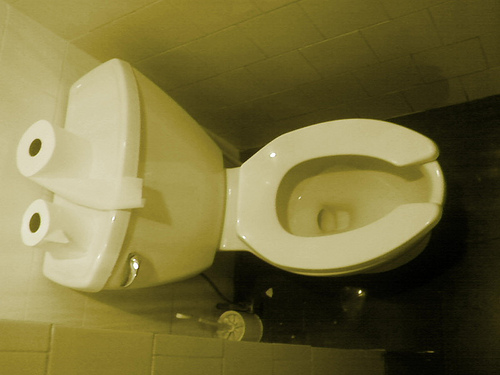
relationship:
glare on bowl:
[255, 151, 295, 166] [245, 142, 433, 254]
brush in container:
[176, 309, 264, 341] [216, 309, 264, 342]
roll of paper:
[19, 199, 78, 255] [8, 119, 96, 201]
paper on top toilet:
[18, 126, 117, 209] [115, 73, 222, 265]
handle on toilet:
[121, 254, 140, 287] [105, 74, 232, 271]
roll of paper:
[19, 199, 78, 255] [5, 112, 103, 251]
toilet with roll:
[43, 58, 447, 293] [19, 199, 78, 255]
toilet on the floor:
[43, 58, 447, 293] [431, 276, 461, 319]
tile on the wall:
[245, 50, 321, 94] [218, 6, 484, 117]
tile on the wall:
[249, 16, 295, 46] [216, 15, 451, 115]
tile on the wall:
[245, 50, 321, 94] [173, 0, 463, 108]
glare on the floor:
[327, 281, 399, 315] [428, 270, 467, 334]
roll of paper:
[19, 199, 78, 255] [60, 162, 140, 221]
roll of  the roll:
[31, 214, 40, 221] [19, 199, 78, 255]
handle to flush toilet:
[121, 254, 140, 287] [41, 49, 452, 319]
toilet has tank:
[33, 51, 471, 335] [37, 51, 229, 323]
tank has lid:
[37, 51, 229, 323] [37, 48, 146, 302]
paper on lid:
[16, 120, 146, 211] [37, 48, 146, 302]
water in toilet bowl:
[284, 169, 415, 230] [229, 107, 455, 283]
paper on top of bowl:
[16, 120, 146, 211] [37, 54, 454, 313]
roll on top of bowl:
[19, 199, 78, 255] [37, 54, 454, 313]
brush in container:
[176, 309, 264, 341] [216, 305, 266, 342]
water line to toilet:
[194, 272, 245, 312] [41, 49, 452, 319]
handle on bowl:
[121, 254, 140, 287] [242, 119, 445, 276]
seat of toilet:
[230, 116, 445, 278] [41, 49, 452, 319]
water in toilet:
[285, 162, 414, 237] [41, 49, 452, 319]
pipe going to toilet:
[201, 299, 260, 313] [41, 49, 452, 319]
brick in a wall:
[50, 327, 153, 369] [21, 62, 351, 364]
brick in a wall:
[153, 333, 224, 359] [13, 312, 385, 365]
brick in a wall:
[153, 333, 224, 359] [4, 317, 399, 366]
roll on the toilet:
[19, 199, 78, 255] [39, 50, 447, 293]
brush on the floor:
[171, 306, 263, 342] [230, 98, 483, 361]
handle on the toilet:
[120, 251, 143, 292] [39, 50, 447, 293]